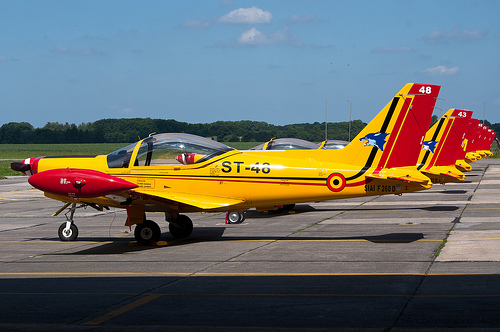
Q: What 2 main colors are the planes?
A: Yellow and red.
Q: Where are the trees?
A: Background.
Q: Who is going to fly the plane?
A: Pilot.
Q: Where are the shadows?
A: On the ground.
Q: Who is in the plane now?
A: No one.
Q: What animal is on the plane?
A: Wolf.